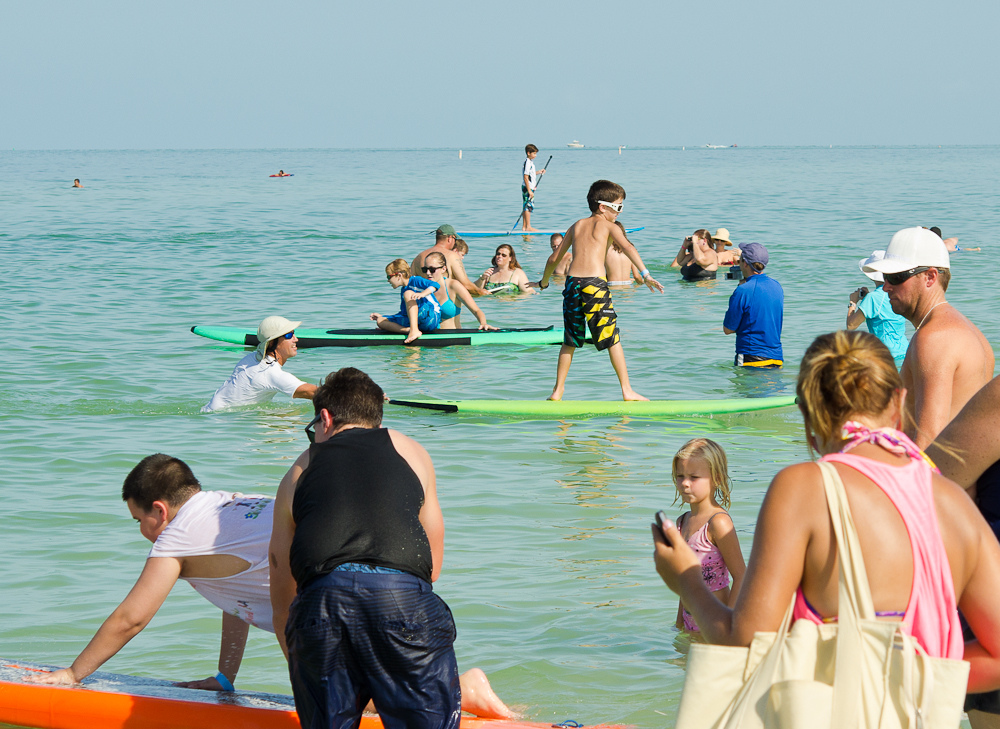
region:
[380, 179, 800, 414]
the boy on the surfboard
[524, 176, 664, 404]
the boy is standing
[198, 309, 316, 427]
the man wearing a hat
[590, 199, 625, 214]
the sunglasses are white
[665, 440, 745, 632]
the girl is standing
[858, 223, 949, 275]
the hat is white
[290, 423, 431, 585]
the thank top is black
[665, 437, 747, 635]
the girl's bathing suit is pink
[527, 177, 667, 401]
the boy is wearing surf shorts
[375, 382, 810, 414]
a green surf board on the water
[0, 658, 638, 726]
an orange surf board on the water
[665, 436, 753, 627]
a little girl in a pink swimsuit in the water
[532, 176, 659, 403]
a little boy in colorful shorts on a surf board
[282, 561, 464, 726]
blue soaking wet shorts on a man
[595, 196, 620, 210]
sunglasses on a boys face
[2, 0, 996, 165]
a blue gray sky at the beach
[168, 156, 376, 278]
the water is blue here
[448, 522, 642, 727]
the water is green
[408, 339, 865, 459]
the surfboard is green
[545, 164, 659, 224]
the boy has brown hair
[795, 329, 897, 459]
Woman with blond hair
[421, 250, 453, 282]
Woman with blond hair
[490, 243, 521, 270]
Woman with brown hair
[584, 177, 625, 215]
Boy with brown hair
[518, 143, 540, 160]
Boy with brown hair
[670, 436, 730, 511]
Girl with blond hair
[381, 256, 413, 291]
Girl with blond hair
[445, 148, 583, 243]
person is standing on a surfboard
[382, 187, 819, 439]
kid standing on a green surfboard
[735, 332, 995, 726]
woman wearing pink tank top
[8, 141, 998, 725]
water is greenish blue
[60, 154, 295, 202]
people out far swimming in the water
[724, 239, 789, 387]
person wearing a blue shirt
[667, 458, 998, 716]
woman has a white carry all bag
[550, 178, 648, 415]
boy wearing white sunglasses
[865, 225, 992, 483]
person wearing a white hat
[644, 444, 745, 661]
little girl dressed in pink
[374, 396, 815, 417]
a long green surfboard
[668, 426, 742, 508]
a girl's short wet hair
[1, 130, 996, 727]
a large body of water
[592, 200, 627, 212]
white and black sunglasses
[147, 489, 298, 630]
a man's white sleeveless shirt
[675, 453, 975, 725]
the top of a woman's bag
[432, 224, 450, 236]
a green cap